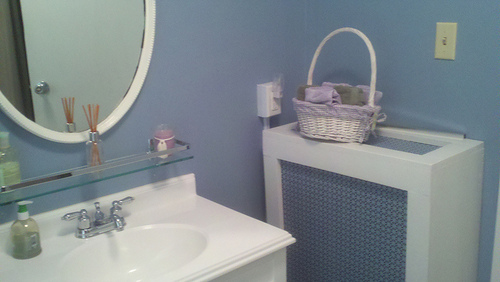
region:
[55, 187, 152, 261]
chrome sink faucet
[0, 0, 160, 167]
white framed mirror in a bathroom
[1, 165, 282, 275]
white sink countertop in a bathroom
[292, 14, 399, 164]
white wicker basket sitting on a counter in a bathroom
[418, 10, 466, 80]
light switch on a bathroom wall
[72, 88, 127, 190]
incense sticks in an incense holder on a shelf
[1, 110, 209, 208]
glass shelf mounted to a bathroom wall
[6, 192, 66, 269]
liquid handsoap in a pump on a sink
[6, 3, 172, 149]
reflection of a doorknob in a bathroom mirror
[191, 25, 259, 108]
blue wall of a bathroom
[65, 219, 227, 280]
Sink on bathroom vanity.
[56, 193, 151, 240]
Hot and cold water faucet on sink.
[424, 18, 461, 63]
Light switch on bathroom wall.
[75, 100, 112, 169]
Aromatherapy Sticks in clear bottle.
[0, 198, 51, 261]
Plastic bottle of hand soap on vanity counter.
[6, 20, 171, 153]
Bottom portion of mirror over sink.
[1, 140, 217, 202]
Glass shelf above sink and below mirror.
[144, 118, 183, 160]
Small pink candle in a glass.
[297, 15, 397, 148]
White and lavender basket sitting on shelf.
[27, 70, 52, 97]
Reflection of door knob in mirror.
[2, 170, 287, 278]
a white bathroom sink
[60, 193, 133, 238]
a chrome bathroom faucet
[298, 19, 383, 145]
a white wicker basket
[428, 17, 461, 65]
an electric wall switch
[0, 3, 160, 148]
a round vanity mirror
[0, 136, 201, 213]
a small glass shelf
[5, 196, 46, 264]
a bottle of soap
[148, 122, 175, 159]
a small pink candle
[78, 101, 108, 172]
wooden scent sticks in bottle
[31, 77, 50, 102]
reflection of a door knob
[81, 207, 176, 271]
the sink is white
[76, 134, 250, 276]
the sink is white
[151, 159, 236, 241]
the sink is white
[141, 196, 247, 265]
the sink is white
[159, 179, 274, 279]
the sink is white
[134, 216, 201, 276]
the sink is white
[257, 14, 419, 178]
a white and purple basket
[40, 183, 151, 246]
a silver faucet on the sink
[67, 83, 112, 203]
a jar of incense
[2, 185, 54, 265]
a soap container on the side of the sink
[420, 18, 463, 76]
light switch on the wall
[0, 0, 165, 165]
a round mirror on the wall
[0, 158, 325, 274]
a sink in the bathroom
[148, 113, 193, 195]
a small candle on the shelf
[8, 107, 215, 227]
a glass shelf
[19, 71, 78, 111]
reflection of a doorknob